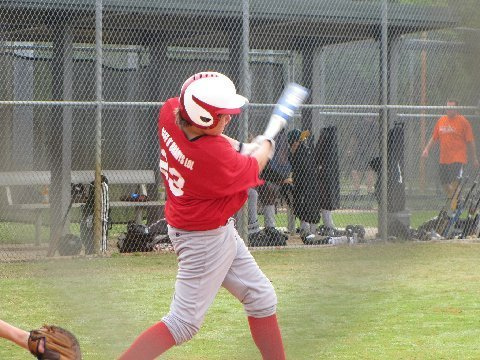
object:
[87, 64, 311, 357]
man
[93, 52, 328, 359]
baseball player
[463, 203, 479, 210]
ball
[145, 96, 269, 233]
uniform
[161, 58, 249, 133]
helmet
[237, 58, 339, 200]
mid-swing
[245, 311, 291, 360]
socks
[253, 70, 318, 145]
bat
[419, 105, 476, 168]
shirt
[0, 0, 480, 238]
fence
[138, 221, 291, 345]
pants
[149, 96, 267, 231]
jersey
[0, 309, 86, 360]
person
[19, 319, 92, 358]
mitt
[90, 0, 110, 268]
pole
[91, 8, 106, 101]
rust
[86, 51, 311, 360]
player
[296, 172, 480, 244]
equipment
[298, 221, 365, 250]
baseball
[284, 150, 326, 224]
jacket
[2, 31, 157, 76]
mesh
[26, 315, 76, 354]
hand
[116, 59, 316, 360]
batter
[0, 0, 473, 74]
dugout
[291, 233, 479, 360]
field